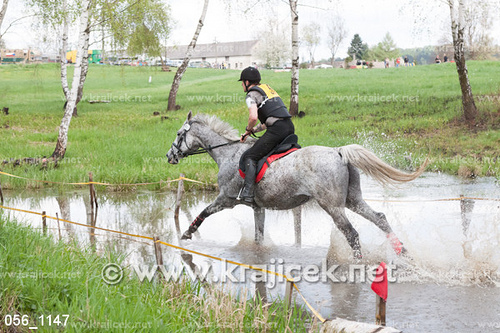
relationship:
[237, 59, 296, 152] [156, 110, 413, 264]
jockey on horse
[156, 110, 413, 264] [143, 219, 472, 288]
horse in water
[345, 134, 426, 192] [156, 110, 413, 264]
tail of horse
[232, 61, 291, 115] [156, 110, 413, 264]
man on horse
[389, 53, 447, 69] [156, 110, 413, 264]
people watching horse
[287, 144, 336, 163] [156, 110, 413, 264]
back of horse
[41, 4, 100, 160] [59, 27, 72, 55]
tree has stem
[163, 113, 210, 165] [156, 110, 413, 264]
head of horse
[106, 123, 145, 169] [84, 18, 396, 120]
grass on plantation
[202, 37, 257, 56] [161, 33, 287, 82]
roof of house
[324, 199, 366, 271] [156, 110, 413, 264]
leg of horse